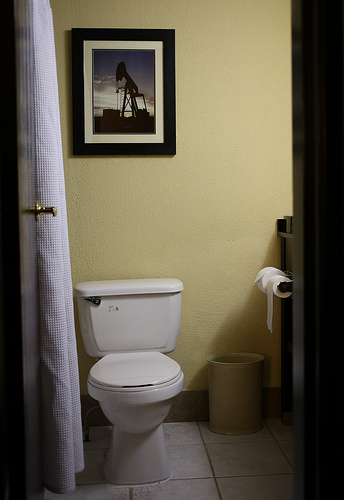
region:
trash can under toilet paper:
[198, 343, 285, 436]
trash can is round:
[205, 348, 275, 434]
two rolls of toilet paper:
[238, 255, 295, 335]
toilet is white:
[83, 278, 189, 491]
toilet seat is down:
[91, 347, 182, 394]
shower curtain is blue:
[8, 0, 98, 497]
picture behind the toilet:
[63, 24, 186, 164]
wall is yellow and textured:
[179, 40, 268, 202]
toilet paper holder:
[278, 277, 303, 297]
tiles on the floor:
[180, 426, 270, 495]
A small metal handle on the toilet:
[82, 293, 106, 308]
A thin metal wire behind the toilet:
[75, 404, 111, 448]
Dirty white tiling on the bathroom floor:
[189, 446, 285, 494]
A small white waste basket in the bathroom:
[203, 348, 270, 438]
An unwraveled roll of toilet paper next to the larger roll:
[265, 275, 292, 330]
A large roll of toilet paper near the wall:
[254, 264, 280, 291]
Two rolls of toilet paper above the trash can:
[255, 265, 298, 319]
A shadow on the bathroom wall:
[206, 300, 286, 414]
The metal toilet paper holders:
[277, 269, 297, 292]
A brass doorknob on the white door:
[34, 200, 69, 223]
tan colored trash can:
[205, 350, 266, 437]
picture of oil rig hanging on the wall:
[69, 27, 178, 157]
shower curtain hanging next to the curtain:
[31, 0, 84, 498]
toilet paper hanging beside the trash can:
[253, 265, 290, 334]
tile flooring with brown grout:
[39, 423, 293, 497]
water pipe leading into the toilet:
[82, 404, 104, 443]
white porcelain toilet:
[72, 277, 181, 486]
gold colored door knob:
[33, 201, 57, 219]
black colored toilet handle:
[80, 295, 104, 305]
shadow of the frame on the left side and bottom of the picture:
[62, 25, 176, 159]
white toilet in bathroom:
[73, 264, 205, 498]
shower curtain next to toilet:
[27, 186, 139, 496]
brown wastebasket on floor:
[187, 318, 284, 470]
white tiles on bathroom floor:
[82, 420, 334, 491]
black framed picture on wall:
[61, 17, 183, 187]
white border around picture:
[72, 34, 168, 177]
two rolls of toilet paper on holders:
[239, 244, 314, 339]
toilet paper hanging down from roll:
[247, 267, 299, 357]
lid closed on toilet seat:
[78, 332, 211, 449]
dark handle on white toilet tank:
[78, 282, 187, 359]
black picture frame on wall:
[68, 22, 178, 172]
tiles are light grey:
[167, 425, 247, 499]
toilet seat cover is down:
[106, 358, 164, 391]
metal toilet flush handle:
[84, 294, 98, 322]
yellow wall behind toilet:
[90, 180, 179, 257]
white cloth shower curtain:
[35, 109, 77, 468]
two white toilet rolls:
[249, 258, 286, 306]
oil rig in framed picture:
[108, 56, 143, 128]